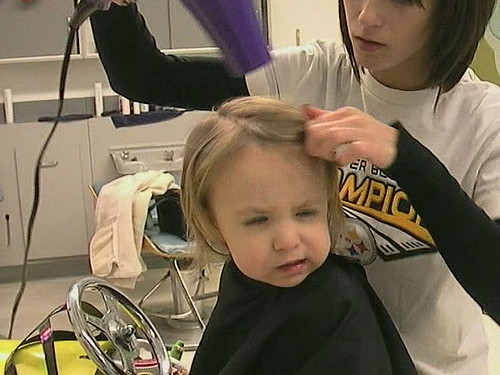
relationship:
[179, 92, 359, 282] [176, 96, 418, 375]
hair belonging to child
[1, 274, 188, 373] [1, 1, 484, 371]
car chair sitting inside hair salon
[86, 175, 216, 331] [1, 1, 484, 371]
chair sitting inside hair salon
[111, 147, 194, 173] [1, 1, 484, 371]
sink built inside hair salon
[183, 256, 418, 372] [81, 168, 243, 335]
smock on chair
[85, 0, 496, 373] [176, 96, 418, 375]
girl with child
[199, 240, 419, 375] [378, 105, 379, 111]
cape protect neck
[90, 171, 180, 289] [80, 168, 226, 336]
smock over chair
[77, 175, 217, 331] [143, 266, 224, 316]
chair with legs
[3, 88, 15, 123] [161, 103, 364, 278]
bottle of hair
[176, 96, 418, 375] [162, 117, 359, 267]
child with hair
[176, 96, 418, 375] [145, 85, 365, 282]
child getting hair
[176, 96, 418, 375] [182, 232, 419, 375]
child wearing cape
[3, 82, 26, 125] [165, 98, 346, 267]
bottle of hair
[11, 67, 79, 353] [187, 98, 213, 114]
cord of blow dryer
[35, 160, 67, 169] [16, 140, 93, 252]
handle for cabinet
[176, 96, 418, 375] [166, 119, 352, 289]
child with hair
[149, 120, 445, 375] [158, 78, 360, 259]
child has hair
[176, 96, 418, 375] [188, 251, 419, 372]
child has cape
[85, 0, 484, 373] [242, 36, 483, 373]
girl has shirt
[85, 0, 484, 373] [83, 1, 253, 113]
girl has shirt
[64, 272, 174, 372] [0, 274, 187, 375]
wheel on car chair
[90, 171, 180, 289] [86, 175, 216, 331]
smock on chair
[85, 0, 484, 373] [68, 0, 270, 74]
girl holds blow dryer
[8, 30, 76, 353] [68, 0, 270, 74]
cord on blow dryer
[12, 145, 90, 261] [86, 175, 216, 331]
drawer behind chair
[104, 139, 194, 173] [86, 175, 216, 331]
sink behind chair